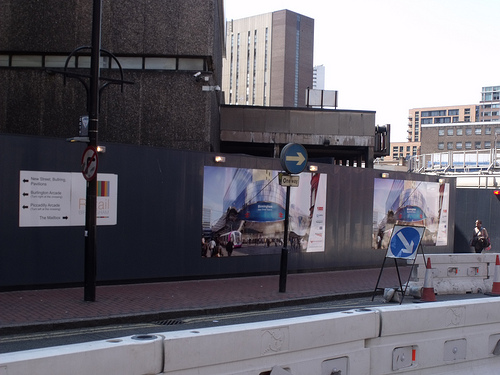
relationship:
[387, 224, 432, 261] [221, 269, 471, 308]
street sign on ground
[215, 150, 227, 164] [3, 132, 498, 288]
light on wall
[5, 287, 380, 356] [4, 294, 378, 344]
street has line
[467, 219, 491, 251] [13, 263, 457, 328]
pedestrian walking along sidewalk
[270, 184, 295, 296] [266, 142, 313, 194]
pole connects along sign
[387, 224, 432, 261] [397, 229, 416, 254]
street sign with arrow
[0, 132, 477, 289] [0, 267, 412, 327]
grey wall beside sidewalk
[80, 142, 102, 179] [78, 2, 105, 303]
sign on post